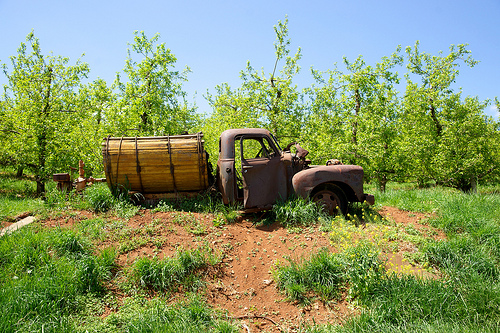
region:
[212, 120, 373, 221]
a rusted abandoned truck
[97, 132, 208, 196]
a role of wooden slats on back of the truck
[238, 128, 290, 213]
door stands ajar on the truck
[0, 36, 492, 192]
a fruit orchard behind the truck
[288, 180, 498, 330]
over grown green grass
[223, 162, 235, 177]
the gas cap on the truck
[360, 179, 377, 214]
a bumper sticks out of the front of the truck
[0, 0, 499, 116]
sunny blue sky with no clouds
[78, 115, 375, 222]
Old junk pick up truck parked in the field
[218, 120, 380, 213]
Old junk pick up truck parked in the field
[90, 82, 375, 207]
Old junk pick up truck parked in the field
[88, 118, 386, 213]
Old junk pick up truck parked in the field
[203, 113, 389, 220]
Old junk pick up truck parked in the field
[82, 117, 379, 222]
Old junk pick up truck parked in the field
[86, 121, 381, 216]
Old junk pick up truck parked in the field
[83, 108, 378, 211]
Old junk pick up truck parked in the field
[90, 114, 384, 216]
Old junk pick up truck parked in the field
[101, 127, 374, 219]
An old truck in an orchard.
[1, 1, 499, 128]
A clear blue sky.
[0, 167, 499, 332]
Green grass on the ground.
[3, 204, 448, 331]
Dirt in the grass.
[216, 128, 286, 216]
The cab of an old truck.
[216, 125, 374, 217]
A old rusted truck.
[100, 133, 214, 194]
A barrel on a truck.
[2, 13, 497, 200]
Trees in an orchard.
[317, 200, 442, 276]
Yellow flowers in a field.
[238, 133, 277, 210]
An old rusted door.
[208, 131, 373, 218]
old rusted broken down truck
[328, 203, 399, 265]
small yellow flowers growing out of dirt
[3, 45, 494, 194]
line of green leafy trees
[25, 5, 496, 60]
clear blue cloudless sky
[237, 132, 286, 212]
open door on passenger side of truck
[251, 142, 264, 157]
steering wheel inside truck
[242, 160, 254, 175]
silver colored handle on truck door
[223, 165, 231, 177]
gas cap on old truck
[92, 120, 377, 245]
an old car in a field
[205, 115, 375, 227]
old car is broken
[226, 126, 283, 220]
the door is open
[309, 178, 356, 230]
front wheel of car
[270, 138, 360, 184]
the hood of car is missing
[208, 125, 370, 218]
the car is rusty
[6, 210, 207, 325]
green grass on the field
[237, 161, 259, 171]
handle of car's door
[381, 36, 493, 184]
the tree is color green